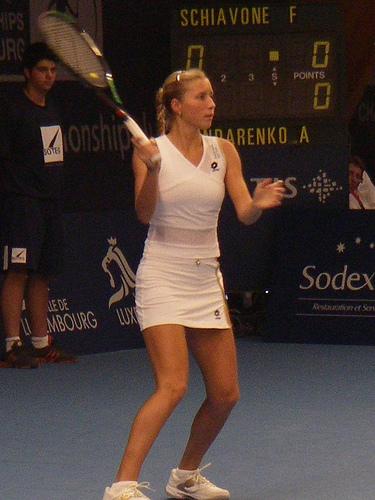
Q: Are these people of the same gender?
A: No, they are both male and female.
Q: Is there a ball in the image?
A: No, there are no balls.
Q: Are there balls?
A: No, there are no balls.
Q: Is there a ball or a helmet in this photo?
A: No, there are no balls or helmets.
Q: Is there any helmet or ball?
A: No, there are no balls or helmets.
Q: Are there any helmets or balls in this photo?
A: No, there are no balls or helmets.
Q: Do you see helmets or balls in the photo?
A: No, there are no balls or helmets.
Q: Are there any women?
A: Yes, there is a woman.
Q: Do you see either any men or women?
A: Yes, there is a woman.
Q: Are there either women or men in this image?
A: Yes, there is a woman.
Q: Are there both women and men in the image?
A: Yes, there are both a woman and a man.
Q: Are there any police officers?
A: No, there are no police officers.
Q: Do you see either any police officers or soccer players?
A: No, there are no police officers or soccer players.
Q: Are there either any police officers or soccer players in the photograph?
A: No, there are no police officers or soccer players.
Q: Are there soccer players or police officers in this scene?
A: No, there are no police officers or soccer players.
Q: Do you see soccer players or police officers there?
A: No, there are no police officers or soccer players.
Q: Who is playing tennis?
A: The woman is playing tennis.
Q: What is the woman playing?
A: The woman is playing tennis.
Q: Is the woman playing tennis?
A: Yes, the woman is playing tennis.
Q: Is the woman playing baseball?
A: No, the woman is playing tennis.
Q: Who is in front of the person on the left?
A: The woman is in front of the man.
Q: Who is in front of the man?
A: The woman is in front of the man.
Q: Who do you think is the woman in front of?
A: The woman is in front of the man.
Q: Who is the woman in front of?
A: The woman is in front of the man.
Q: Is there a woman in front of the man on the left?
A: Yes, there is a woman in front of the man.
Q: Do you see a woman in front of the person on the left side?
A: Yes, there is a woman in front of the man.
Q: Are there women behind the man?
A: No, the woman is in front of the man.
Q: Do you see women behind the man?
A: No, the woman is in front of the man.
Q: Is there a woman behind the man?
A: No, the woman is in front of the man.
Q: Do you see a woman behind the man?
A: No, the woman is in front of the man.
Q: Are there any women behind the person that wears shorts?
A: No, the woman is in front of the man.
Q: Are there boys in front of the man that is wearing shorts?
A: No, there is a woman in front of the man.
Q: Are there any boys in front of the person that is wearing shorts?
A: No, there is a woman in front of the man.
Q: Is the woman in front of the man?
A: Yes, the woman is in front of the man.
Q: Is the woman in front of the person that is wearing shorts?
A: Yes, the woman is in front of the man.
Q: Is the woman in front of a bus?
A: No, the woman is in front of the man.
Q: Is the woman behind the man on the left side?
A: No, the woman is in front of the man.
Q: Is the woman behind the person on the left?
A: No, the woman is in front of the man.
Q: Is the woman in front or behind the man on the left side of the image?
A: The woman is in front of the man.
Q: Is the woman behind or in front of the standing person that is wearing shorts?
A: The woman is in front of the man.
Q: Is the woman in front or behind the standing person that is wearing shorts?
A: The woman is in front of the man.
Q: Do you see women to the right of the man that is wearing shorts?
A: Yes, there is a woman to the right of the man.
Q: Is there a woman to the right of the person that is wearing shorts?
A: Yes, there is a woman to the right of the man.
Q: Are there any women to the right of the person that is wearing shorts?
A: Yes, there is a woman to the right of the man.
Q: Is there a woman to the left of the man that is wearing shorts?
A: No, the woman is to the right of the man.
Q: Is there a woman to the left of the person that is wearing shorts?
A: No, the woman is to the right of the man.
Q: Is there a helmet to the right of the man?
A: No, there is a woman to the right of the man.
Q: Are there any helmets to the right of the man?
A: No, there is a woman to the right of the man.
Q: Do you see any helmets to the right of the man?
A: No, there is a woman to the right of the man.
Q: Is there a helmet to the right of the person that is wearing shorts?
A: No, there is a woman to the right of the man.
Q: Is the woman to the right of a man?
A: Yes, the woman is to the right of a man.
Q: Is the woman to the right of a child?
A: No, the woman is to the right of a man.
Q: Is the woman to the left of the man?
A: No, the woman is to the right of the man.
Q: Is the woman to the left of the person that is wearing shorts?
A: No, the woman is to the right of the man.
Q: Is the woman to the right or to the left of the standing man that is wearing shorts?
A: The woman is to the right of the man.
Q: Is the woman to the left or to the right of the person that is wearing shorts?
A: The woman is to the right of the man.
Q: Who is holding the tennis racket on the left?
A: The woman is holding the racket.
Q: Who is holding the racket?
A: The woman is holding the racket.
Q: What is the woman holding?
A: The woman is holding the tennis racket.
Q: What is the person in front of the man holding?
A: The woman is holding the tennis racket.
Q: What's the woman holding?
A: The woman is holding the tennis racket.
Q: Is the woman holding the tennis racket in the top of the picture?
A: Yes, the woman is holding the racket.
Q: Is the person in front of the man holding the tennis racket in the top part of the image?
A: Yes, the woman is holding the racket.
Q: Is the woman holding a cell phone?
A: No, the woman is holding the racket.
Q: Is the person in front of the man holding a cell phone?
A: No, the woman is holding the racket.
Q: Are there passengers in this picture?
A: No, there are no passengers.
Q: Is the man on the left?
A: Yes, the man is on the left of the image.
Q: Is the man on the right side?
A: No, the man is on the left of the image.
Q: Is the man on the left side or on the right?
A: The man is on the left of the image.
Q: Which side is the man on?
A: The man is on the left of the image.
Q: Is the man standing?
A: Yes, the man is standing.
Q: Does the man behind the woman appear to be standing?
A: Yes, the man is standing.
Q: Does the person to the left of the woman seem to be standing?
A: Yes, the man is standing.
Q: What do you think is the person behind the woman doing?
A: The man is standing.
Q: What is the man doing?
A: The man is standing.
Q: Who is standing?
A: The man is standing.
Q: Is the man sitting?
A: No, the man is standing.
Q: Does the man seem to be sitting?
A: No, the man is standing.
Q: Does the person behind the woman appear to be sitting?
A: No, the man is standing.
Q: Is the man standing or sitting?
A: The man is standing.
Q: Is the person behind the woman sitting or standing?
A: The man is standing.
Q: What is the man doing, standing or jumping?
A: The man is standing.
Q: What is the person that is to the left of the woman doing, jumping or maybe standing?
A: The man is standing.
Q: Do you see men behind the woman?
A: Yes, there is a man behind the woman.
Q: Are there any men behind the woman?
A: Yes, there is a man behind the woman.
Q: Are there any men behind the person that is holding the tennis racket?
A: Yes, there is a man behind the woman.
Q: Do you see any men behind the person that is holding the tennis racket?
A: Yes, there is a man behind the woman.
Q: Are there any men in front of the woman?
A: No, the man is behind the woman.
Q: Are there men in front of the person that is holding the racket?
A: No, the man is behind the woman.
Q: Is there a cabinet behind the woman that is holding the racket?
A: No, there is a man behind the woman.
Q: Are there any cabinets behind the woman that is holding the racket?
A: No, there is a man behind the woman.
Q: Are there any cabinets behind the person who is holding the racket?
A: No, there is a man behind the woman.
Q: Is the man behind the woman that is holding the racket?
A: Yes, the man is behind the woman.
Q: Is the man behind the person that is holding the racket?
A: Yes, the man is behind the woman.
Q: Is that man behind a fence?
A: No, the man is behind the woman.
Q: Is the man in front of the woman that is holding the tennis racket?
A: No, the man is behind the woman.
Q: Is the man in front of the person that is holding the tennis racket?
A: No, the man is behind the woman.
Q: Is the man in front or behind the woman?
A: The man is behind the woman.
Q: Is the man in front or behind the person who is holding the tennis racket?
A: The man is behind the woman.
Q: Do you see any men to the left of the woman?
A: Yes, there is a man to the left of the woman.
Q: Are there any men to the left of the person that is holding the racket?
A: Yes, there is a man to the left of the woman.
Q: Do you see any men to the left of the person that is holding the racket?
A: Yes, there is a man to the left of the woman.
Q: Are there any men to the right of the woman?
A: No, the man is to the left of the woman.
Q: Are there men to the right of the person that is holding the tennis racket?
A: No, the man is to the left of the woman.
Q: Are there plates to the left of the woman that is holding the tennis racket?
A: No, there is a man to the left of the woman.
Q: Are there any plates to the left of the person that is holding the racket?
A: No, there is a man to the left of the woman.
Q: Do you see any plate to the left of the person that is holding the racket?
A: No, there is a man to the left of the woman.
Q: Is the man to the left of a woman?
A: Yes, the man is to the left of a woman.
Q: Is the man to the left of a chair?
A: No, the man is to the left of a woman.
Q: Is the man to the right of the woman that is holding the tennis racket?
A: No, the man is to the left of the woman.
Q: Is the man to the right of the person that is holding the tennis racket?
A: No, the man is to the left of the woman.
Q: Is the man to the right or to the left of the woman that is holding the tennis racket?
A: The man is to the left of the woman.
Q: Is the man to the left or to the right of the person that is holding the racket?
A: The man is to the left of the woman.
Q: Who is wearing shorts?
A: The man is wearing shorts.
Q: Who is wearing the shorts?
A: The man is wearing shorts.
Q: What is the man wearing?
A: The man is wearing shorts.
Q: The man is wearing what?
A: The man is wearing shorts.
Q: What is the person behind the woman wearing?
A: The man is wearing shorts.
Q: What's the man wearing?
A: The man is wearing shorts.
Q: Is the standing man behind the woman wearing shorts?
A: Yes, the man is wearing shorts.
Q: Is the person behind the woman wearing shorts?
A: Yes, the man is wearing shorts.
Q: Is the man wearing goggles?
A: No, the man is wearing shorts.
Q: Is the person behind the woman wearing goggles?
A: No, the man is wearing shorts.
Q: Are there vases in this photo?
A: No, there are no vases.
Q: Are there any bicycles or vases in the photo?
A: No, there are no vases or bicycles.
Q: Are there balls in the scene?
A: No, there are no balls.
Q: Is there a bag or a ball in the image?
A: No, there are no balls or bags.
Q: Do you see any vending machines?
A: No, there are no vending machines.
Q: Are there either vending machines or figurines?
A: No, there are no vending machines or figurines.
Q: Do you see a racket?
A: Yes, there is a racket.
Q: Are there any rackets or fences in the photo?
A: Yes, there is a racket.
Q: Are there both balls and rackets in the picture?
A: No, there is a racket but no balls.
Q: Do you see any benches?
A: No, there are no benches.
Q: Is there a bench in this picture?
A: No, there are no benches.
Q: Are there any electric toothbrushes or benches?
A: No, there are no benches or electric toothbrushes.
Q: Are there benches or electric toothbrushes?
A: No, there are no benches or electric toothbrushes.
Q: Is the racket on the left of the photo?
A: Yes, the racket is on the left of the image.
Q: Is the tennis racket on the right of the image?
A: No, the tennis racket is on the left of the image.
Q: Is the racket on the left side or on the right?
A: The racket is on the left of the image.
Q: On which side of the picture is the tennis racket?
A: The tennis racket is on the left of the image.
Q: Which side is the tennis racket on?
A: The tennis racket is on the left of the image.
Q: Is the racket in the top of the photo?
A: Yes, the racket is in the top of the image.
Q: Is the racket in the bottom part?
A: No, the racket is in the top of the image.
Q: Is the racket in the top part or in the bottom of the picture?
A: The racket is in the top of the image.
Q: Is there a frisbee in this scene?
A: No, there are no frisbees.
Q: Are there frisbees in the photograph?
A: No, there are no frisbees.